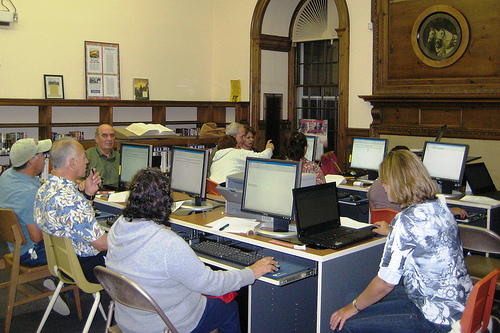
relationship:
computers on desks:
[244, 155, 295, 226] [153, 172, 388, 281]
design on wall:
[412, 4, 479, 73] [383, 19, 498, 114]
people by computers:
[26, 115, 483, 269] [244, 155, 295, 226]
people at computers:
[26, 115, 483, 269] [244, 155, 295, 226]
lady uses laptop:
[362, 143, 495, 320] [290, 193, 371, 251]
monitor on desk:
[175, 139, 212, 204] [153, 172, 388, 281]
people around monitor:
[26, 115, 483, 269] [175, 139, 212, 204]